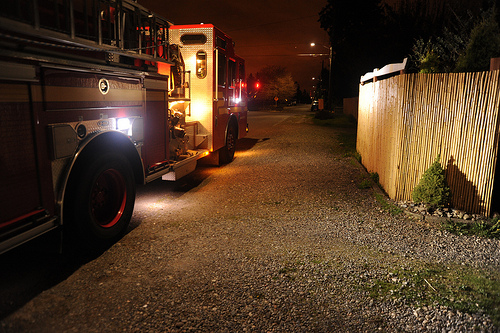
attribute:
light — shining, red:
[108, 113, 141, 136]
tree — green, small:
[409, 156, 456, 210]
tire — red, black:
[75, 144, 148, 235]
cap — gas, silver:
[97, 80, 113, 94]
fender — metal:
[52, 130, 154, 202]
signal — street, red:
[249, 77, 263, 93]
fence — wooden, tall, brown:
[347, 72, 489, 210]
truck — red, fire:
[5, 0, 259, 216]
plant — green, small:
[412, 26, 446, 66]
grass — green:
[451, 271, 493, 294]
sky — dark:
[219, 3, 299, 66]